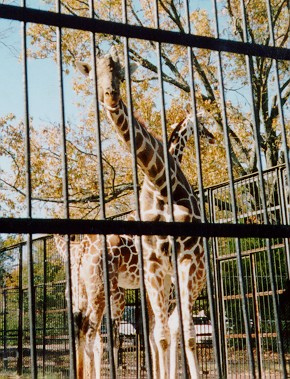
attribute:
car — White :
[191, 314, 214, 345]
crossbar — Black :
[5, 10, 289, 54]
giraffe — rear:
[43, 218, 127, 377]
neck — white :
[152, 128, 188, 177]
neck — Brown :
[107, 104, 177, 197]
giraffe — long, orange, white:
[81, 33, 227, 258]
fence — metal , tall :
[5, 7, 288, 350]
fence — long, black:
[0, 236, 285, 378]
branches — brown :
[134, 42, 220, 108]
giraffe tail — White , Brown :
[71, 241, 85, 336]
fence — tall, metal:
[10, 6, 279, 375]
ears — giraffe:
[69, 52, 137, 78]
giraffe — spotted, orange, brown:
[31, 40, 243, 373]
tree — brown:
[30, 1, 288, 162]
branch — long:
[235, 14, 274, 125]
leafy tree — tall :
[16, 1, 283, 224]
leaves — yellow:
[18, 18, 287, 216]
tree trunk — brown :
[205, 179, 281, 231]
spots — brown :
[118, 242, 131, 262]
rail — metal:
[221, 289, 285, 301]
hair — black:
[70, 307, 87, 328]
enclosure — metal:
[4, 3, 288, 376]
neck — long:
[94, 79, 189, 207]